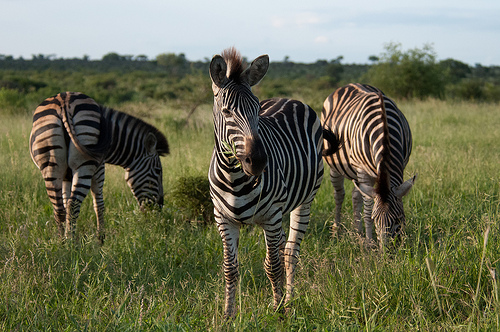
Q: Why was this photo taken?
A: For a magazine.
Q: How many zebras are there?
A: Three.